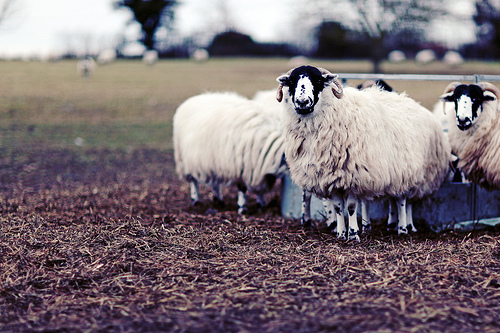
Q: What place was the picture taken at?
A: It was taken at the yard.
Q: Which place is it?
A: It is a yard.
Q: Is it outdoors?
A: Yes, it is outdoors.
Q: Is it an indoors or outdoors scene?
A: It is outdoors.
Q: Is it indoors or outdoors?
A: It is outdoors.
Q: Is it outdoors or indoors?
A: It is outdoors.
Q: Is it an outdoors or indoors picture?
A: It is outdoors.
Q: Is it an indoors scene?
A: No, it is outdoors.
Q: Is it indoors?
A: No, it is outdoors.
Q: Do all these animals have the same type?
A: Yes, all the animals are sheep.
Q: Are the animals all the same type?
A: Yes, all the animals are sheep.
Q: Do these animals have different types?
A: No, all the animals are sheep.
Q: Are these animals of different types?
A: No, all the animals are sheep.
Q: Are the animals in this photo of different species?
A: No, all the animals are sheep.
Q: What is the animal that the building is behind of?
A: The animal is a sheep.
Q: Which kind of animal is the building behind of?
A: The building is behind the sheep.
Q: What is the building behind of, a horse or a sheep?
A: The building is behind a sheep.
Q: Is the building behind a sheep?
A: Yes, the building is behind a sheep.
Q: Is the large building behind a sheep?
A: Yes, the building is behind a sheep.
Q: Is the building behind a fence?
A: No, the building is behind a sheep.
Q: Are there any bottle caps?
A: No, there are no bottle caps.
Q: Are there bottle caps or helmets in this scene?
A: No, there are no bottle caps or helmets.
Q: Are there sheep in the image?
A: Yes, there is a sheep.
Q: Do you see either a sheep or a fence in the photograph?
A: Yes, there is a sheep.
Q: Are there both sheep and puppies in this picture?
A: No, there is a sheep but no puppies.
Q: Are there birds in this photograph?
A: No, there are no birds.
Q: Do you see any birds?
A: No, there are no birds.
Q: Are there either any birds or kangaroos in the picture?
A: No, there are no birds or kangaroos.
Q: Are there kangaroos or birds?
A: No, there are no birds or kangaroos.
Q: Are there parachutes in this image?
A: No, there are no parachutes.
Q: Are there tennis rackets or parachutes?
A: No, there are no parachutes or tennis rackets.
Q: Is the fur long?
A: Yes, the fur is long.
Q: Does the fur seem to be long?
A: Yes, the fur is long.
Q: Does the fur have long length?
A: Yes, the fur is long.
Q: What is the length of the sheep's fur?
A: The fur is long.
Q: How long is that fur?
A: The fur is long.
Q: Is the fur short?
A: No, the fur is long.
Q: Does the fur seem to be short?
A: No, the fur is long.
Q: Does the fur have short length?
A: No, the fur is long.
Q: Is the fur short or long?
A: The fur is long.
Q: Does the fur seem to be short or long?
A: The fur is long.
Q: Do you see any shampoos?
A: No, there are no shampoos.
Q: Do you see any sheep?
A: Yes, there is a sheep.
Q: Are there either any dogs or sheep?
A: Yes, there is a sheep.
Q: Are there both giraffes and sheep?
A: No, there is a sheep but no giraffes.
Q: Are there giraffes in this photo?
A: No, there are no giraffes.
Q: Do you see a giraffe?
A: No, there are no giraffes.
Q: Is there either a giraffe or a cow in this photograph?
A: No, there are no giraffes or cows.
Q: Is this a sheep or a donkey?
A: This is a sheep.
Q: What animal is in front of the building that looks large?
A: The sheep is in front of the building.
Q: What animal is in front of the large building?
A: The animal is a sheep.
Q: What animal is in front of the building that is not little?
A: The animal is a sheep.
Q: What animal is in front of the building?
A: The animal is a sheep.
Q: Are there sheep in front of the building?
A: Yes, there is a sheep in front of the building.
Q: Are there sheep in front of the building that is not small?
A: Yes, there is a sheep in front of the building.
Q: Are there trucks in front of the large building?
A: No, there is a sheep in front of the building.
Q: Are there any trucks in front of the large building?
A: No, there is a sheep in front of the building.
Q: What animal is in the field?
A: The sheep is in the field.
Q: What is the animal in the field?
A: The animal is a sheep.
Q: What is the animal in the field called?
A: The animal is a sheep.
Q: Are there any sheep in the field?
A: Yes, there is a sheep in the field.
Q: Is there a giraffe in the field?
A: No, there is a sheep in the field.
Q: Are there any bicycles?
A: No, there are no bicycles.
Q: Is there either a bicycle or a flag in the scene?
A: No, there are no bicycles or flags.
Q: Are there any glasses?
A: No, there are no glasses.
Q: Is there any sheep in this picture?
A: Yes, there is a sheep.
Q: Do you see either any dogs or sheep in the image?
A: Yes, there is a sheep.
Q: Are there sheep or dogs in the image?
A: Yes, there is a sheep.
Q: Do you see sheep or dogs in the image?
A: Yes, there is a sheep.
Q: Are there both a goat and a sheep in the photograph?
A: No, there is a sheep but no goats.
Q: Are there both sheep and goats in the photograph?
A: No, there is a sheep but no goats.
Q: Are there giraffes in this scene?
A: No, there are no giraffes.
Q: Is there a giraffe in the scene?
A: No, there are no giraffes.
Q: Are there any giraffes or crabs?
A: No, there are no giraffes or crabs.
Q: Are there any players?
A: No, there are no players.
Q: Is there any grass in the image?
A: Yes, there is grass.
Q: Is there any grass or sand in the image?
A: Yes, there is grass.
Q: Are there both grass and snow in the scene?
A: No, there is grass but no snow.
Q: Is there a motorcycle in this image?
A: No, there are no motorcycles.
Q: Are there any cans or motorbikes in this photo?
A: No, there are no motorbikes or cans.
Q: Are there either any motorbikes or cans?
A: No, there are no motorbikes or cans.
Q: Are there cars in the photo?
A: No, there are no cars.